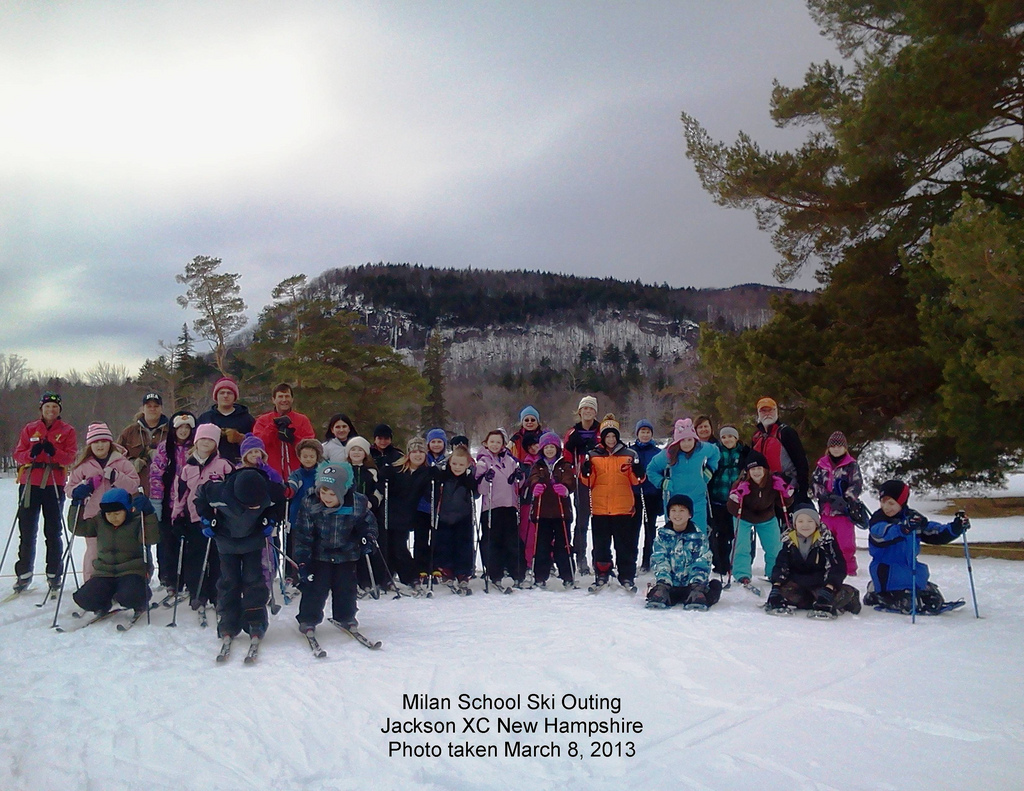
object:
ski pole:
[48, 463, 83, 595]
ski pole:
[0, 459, 39, 576]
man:
[12, 391, 80, 593]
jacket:
[12, 415, 79, 488]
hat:
[213, 376, 240, 403]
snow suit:
[645, 440, 722, 535]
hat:
[667, 418, 700, 460]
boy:
[67, 483, 161, 620]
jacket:
[67, 497, 162, 581]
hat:
[97, 486, 136, 520]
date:
[503, 737, 637, 761]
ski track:
[602, 615, 950, 786]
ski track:
[391, 643, 448, 784]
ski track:
[143, 679, 306, 784]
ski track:
[68, 705, 118, 791]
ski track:
[0, 630, 45, 708]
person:
[579, 411, 648, 595]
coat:
[579, 442, 641, 516]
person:
[65, 419, 145, 582]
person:
[117, 392, 170, 585]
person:
[149, 409, 199, 587]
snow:
[2, 476, 1023, 789]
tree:
[683, 312, 798, 450]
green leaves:
[197, 268, 208, 273]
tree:
[173, 253, 248, 384]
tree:
[419, 327, 453, 440]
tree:
[171, 319, 200, 423]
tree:
[236, 272, 435, 450]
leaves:
[947, 346, 953, 351]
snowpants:
[732, 516, 782, 584]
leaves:
[323, 342, 333, 346]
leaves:
[854, 280, 865, 288]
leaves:
[825, 330, 833, 337]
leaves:
[860, 264, 871, 266]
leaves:
[874, 308, 882, 317]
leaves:
[777, 335, 780, 337]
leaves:
[690, 120, 696, 130]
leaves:
[699, 136, 705, 146]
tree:
[683, 0, 1024, 476]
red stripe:
[902, 492, 906, 497]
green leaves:
[869, 278, 894, 290]